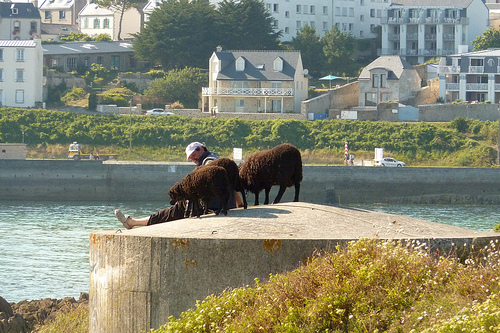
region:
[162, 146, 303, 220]
two brown sheep on a ledge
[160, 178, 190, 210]
the head of a brown sheep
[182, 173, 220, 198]
the fur of a brown sheep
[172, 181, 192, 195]
the neck of a brown sheep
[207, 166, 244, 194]
the tail of a brown sheep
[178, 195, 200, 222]
the front legs of a brown sheep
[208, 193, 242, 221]
the hind legs of a brown sheep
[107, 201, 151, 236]
the feet of a person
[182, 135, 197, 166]
the head of a person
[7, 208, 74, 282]
the ripples in a river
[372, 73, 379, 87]
glass window on building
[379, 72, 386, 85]
glass window on building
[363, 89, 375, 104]
glass window on building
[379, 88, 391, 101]
glass window on building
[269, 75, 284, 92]
glass window on building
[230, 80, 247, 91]
glass window on building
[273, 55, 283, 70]
glass window on building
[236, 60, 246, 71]
glass window on building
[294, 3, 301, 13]
glass window on building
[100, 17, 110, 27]
glass window on building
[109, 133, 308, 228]
man with three brown sheep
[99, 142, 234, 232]
man sitting on cement pier near river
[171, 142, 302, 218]
three chocolate brown sheep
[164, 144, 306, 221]
three sheep are standing on a cement pier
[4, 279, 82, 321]
rocks are near the water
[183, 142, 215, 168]
man with three sheep wearing baseball hat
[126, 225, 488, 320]
brush and weeds near the cement pier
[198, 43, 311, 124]
house is across the river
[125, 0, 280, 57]
large green trees behind the house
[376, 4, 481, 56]
large building with many balconies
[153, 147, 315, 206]
three sheep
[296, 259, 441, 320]
the green grass and white flowers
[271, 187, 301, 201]
back legs of the sheep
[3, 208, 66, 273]
the water is blue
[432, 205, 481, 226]
the water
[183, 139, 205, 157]
man is wearing a hat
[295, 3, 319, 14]
windows on the building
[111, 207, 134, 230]
the man is wearing a shoe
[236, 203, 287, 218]
a shadow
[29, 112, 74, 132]
the bushes are green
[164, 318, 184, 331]
green grass on ground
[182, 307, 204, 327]
green grass on ground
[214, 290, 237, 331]
green grass on ground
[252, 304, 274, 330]
green grass on ground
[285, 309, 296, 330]
green grass on ground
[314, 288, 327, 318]
green grass on ground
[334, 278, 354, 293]
green grass on ground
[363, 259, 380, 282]
green grass on ground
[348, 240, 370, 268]
green grass on ground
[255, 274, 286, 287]
green grass on ground